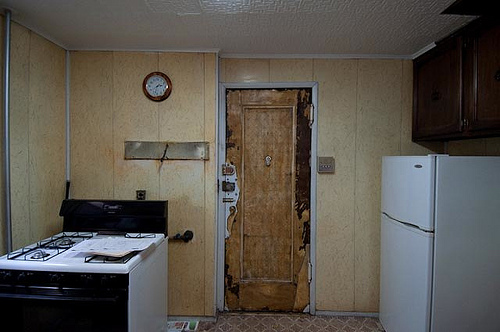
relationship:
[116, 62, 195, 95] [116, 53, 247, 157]
clock on wall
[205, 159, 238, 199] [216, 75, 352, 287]
locks on door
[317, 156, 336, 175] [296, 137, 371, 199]
intercom of intercom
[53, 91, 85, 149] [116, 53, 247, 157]
pipe along wall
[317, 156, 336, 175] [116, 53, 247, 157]
intercom on wall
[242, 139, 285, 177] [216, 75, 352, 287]
hole in door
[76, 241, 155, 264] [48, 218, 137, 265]
papers on stove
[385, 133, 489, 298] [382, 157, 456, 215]
fridge has freezer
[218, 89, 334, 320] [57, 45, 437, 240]
doorway to kitchen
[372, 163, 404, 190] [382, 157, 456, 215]
door of freezer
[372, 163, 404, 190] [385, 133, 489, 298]
door of fridge